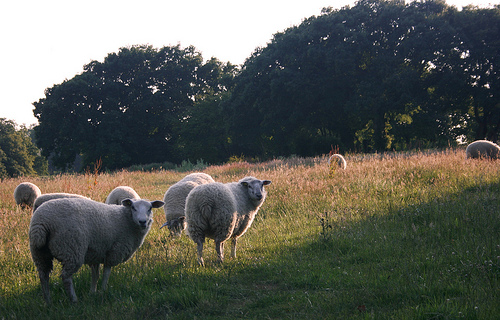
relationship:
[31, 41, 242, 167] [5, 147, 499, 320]
tree in field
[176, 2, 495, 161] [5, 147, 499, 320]
tree in field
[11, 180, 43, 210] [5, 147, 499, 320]
sheep in field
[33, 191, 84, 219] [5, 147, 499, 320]
sheep in field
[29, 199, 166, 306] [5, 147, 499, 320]
sheep in field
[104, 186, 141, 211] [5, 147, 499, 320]
sheep in field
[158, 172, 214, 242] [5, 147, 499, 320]
sheep in field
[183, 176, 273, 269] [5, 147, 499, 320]
sheep in field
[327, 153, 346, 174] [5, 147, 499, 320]
sheep in field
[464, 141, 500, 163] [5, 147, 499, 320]
sheep in field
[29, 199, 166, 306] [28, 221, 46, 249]
sheep has tail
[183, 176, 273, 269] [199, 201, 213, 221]
sheep has tail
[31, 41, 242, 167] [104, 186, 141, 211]
tree behind sheep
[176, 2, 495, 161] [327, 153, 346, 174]
tree behind sheep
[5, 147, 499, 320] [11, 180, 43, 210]
field has sheep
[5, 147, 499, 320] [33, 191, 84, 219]
field has sheep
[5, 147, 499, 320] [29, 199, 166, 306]
field has sheep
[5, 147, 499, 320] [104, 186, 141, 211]
field has sheep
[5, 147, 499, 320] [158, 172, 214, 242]
field has sheep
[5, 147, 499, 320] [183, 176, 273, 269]
field has sheep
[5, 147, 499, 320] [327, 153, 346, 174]
field has sheep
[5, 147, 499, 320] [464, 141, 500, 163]
field has sheep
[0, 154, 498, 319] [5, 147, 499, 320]
grass in field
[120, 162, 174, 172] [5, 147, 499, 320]
bush in field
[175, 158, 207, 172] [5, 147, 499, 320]
weeds in field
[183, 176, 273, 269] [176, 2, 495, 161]
sheep running to tree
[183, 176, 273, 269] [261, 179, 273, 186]
sheep has ears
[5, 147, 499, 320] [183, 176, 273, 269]
field with sheep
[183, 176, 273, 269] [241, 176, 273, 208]
sheep has head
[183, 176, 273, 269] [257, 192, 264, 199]
sheep has nose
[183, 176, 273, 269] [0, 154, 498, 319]
sheep in grass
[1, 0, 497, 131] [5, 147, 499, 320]
sky over field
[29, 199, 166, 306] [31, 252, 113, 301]
sheep has legs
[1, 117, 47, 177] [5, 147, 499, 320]
tree in field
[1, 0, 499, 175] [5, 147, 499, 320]
wooded area near field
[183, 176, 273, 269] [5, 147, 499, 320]
sheep grazing in field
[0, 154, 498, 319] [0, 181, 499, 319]
grass in shadows